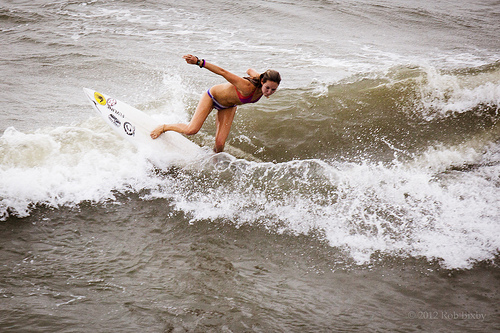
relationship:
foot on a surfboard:
[150, 125, 167, 140] [70, 71, 210, 196]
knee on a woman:
[181, 117, 204, 149] [149, 54, 281, 163]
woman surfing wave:
[214, 51, 321, 132] [0, 30, 499, 276]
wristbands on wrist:
[187, 51, 219, 81] [196, 48, 212, 80]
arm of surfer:
[239, 60, 268, 92] [219, 53, 308, 134]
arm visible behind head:
[239, 60, 268, 92] [245, 62, 288, 107]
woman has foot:
[149, 54, 281, 163] [150, 122, 167, 140]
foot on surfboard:
[150, 122, 167, 140] [79, 81, 209, 177]